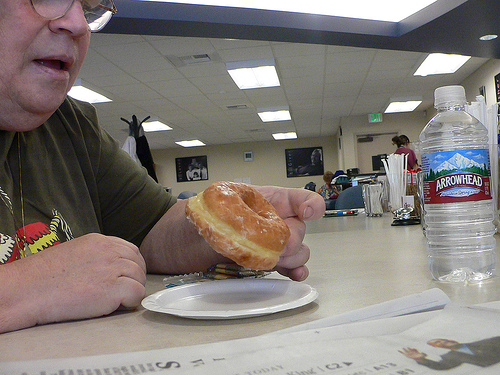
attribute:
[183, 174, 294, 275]
donut — glazed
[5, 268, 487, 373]
newspaper — open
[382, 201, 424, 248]
bell — shiny, silver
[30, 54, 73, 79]
mouth — open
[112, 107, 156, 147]
coat rack — tall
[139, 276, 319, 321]
plate — white